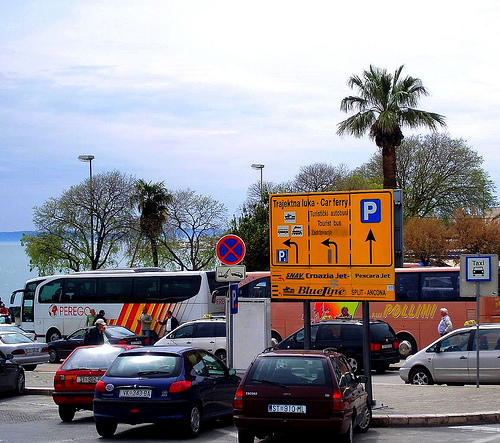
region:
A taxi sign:
[453, 250, 497, 284]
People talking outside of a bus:
[81, 307, 179, 342]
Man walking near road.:
[76, 316, 113, 363]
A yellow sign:
[266, 189, 393, 297]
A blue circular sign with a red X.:
[206, 232, 256, 269]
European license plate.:
[261, 398, 313, 418]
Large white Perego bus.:
[31, 271, 241, 348]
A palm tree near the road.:
[123, 178, 192, 275]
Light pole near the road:
[61, 146, 112, 274]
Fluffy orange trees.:
[399, 212, 498, 264]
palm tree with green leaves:
[333, 65, 447, 187]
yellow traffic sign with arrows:
[268, 187, 397, 300]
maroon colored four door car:
[231, 347, 375, 442]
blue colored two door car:
[91, 343, 248, 436]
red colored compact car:
[46, 341, 118, 423]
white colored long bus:
[10, 268, 220, 342]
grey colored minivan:
[401, 317, 498, 392]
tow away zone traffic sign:
[213, 263, 246, 285]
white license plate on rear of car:
[263, 401, 308, 417]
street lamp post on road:
[76, 144, 101, 272]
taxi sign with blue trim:
[464, 253, 492, 281]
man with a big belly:
[432, 306, 457, 353]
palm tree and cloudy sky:
[335, 58, 451, 184]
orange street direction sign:
[268, 192, 395, 304]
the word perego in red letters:
[55, 303, 96, 320]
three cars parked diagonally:
[50, 335, 384, 441]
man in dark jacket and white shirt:
[155, 307, 195, 337]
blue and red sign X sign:
[212, 231, 253, 267]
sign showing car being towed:
[213, 262, 252, 282]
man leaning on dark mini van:
[273, 313, 405, 371]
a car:
[256, 353, 327, 438]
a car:
[218, 310, 280, 417]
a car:
[262, 372, 304, 439]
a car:
[251, 315, 300, 427]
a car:
[296, 385, 308, 436]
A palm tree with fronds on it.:
[333, 45, 458, 183]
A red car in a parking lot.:
[221, 338, 381, 439]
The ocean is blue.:
[2, 248, 27, 283]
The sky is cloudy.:
[11, 15, 296, 143]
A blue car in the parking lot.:
[92, 345, 228, 433]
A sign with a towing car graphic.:
[191, 216, 258, 303]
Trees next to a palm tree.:
[11, 170, 221, 268]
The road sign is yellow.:
[251, 160, 414, 318]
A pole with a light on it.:
[238, 150, 274, 193]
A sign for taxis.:
[442, 237, 498, 381]